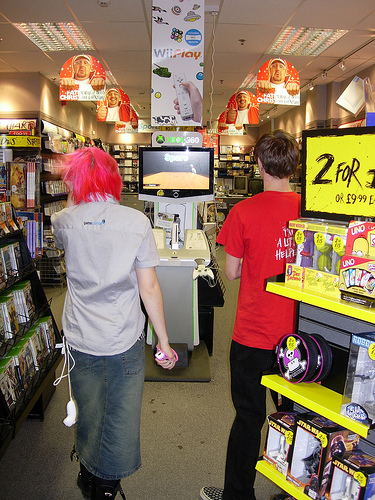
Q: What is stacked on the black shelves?
A: Video games.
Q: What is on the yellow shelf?
A: Star Wars toys.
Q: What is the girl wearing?
A: A long jean skirt.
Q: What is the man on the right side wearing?
A: Red shirt and black pants.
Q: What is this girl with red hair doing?
A: Playing video games.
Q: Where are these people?
A: In a video games store.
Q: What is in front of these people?
A: A video monitor.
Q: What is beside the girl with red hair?
A: Xbox 360 video game display.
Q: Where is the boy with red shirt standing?
A: Next to the girl with red hair.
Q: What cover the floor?
A: Carpet.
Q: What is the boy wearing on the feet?
A: Black and white shoes.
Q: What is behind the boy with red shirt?
A: Yellow shelves.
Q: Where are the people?
A: In a store.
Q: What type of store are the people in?
A: A video game store.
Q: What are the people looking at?
A: A television.